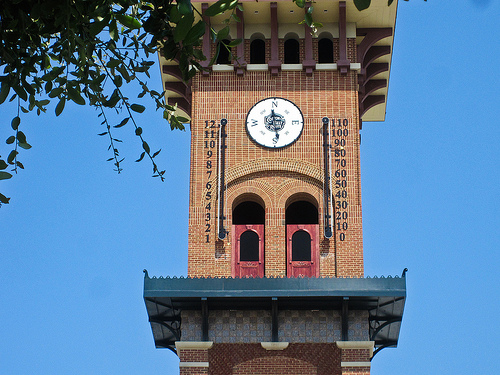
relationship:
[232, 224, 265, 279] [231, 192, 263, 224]
door with window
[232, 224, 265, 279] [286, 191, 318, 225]
door has window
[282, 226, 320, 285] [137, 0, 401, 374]
door on building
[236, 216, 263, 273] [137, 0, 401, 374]
door on building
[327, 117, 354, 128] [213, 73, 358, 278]
number on brick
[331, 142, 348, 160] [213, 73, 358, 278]
number on brick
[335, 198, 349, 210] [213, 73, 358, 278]
number on brick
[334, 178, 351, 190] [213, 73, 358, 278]
number on brick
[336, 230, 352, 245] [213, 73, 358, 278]
number on brick